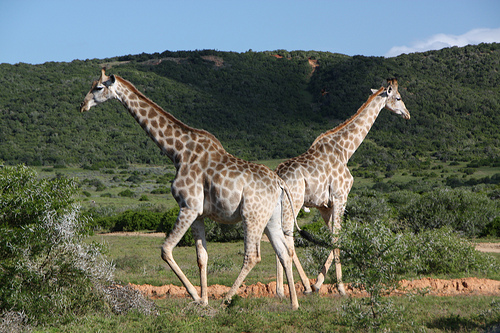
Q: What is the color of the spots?
A: Brown.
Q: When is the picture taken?
A: Daytime.